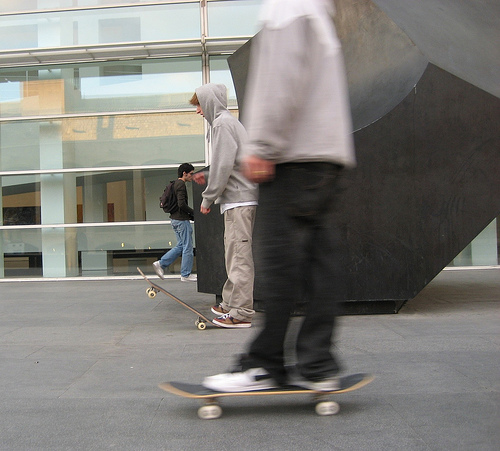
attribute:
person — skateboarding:
[202, 18, 348, 391]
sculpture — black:
[226, 1, 500, 320]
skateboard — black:
[132, 260, 215, 330]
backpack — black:
[152, 176, 179, 219]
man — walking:
[153, 158, 193, 283]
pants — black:
[237, 159, 352, 387]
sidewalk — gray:
[0, 274, 500, 449]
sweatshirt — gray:
[197, 79, 262, 210]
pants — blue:
[156, 216, 203, 282]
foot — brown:
[210, 311, 261, 328]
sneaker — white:
[202, 360, 279, 401]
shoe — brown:
[214, 312, 249, 326]